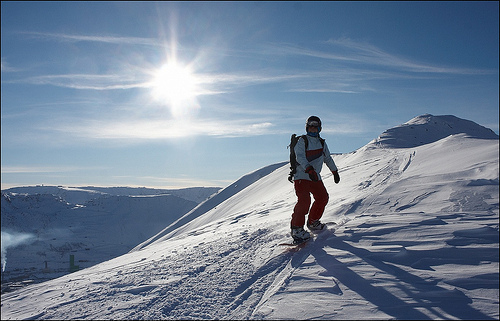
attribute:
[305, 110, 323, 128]
cap — red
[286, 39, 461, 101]
clouds — wispy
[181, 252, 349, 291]
snow — white